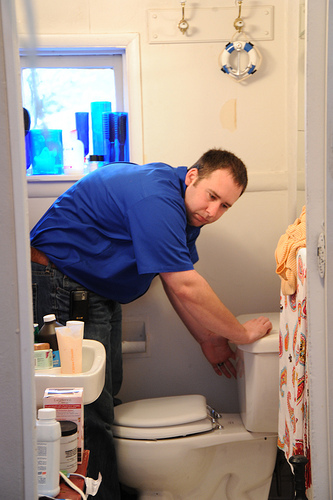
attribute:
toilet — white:
[110, 306, 298, 497]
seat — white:
[106, 387, 225, 471]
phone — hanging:
[66, 286, 94, 327]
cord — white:
[61, 472, 84, 495]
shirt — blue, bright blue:
[33, 154, 207, 312]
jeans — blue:
[30, 229, 138, 498]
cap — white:
[40, 313, 58, 325]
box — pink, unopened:
[40, 387, 89, 469]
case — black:
[67, 282, 92, 318]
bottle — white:
[60, 419, 83, 479]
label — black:
[63, 446, 80, 471]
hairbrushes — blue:
[102, 108, 126, 168]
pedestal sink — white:
[37, 332, 110, 408]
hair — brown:
[186, 146, 254, 199]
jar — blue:
[96, 108, 135, 169]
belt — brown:
[32, 246, 55, 272]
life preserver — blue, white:
[31, 101, 63, 178]